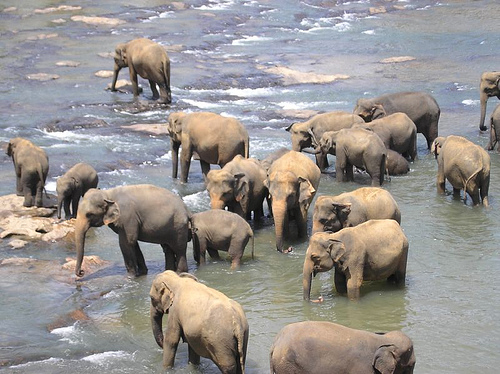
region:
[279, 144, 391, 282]
The elephants are visible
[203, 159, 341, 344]
The elephants are visible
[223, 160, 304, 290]
The elephants are visible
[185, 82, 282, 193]
The elephants are visible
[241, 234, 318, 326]
The elephants are visible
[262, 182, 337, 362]
The elephants are visible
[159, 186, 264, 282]
The elephants are visible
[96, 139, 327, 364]
The elephants are visible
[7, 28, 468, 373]
Many elephants are in the water.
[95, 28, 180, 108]
The elephant is drinking water.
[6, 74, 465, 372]
The elephants are grey.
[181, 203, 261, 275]
This is a baby elephant.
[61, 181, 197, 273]
The elephant is grey.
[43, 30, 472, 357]
The water is shallow.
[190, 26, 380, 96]
The water is moving.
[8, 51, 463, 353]
The elephants are together.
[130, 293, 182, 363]
The trunk is long.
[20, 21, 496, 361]
The sun is shining.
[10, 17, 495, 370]
herd of asian female elephants with young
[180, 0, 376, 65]
white caps on the water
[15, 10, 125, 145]
Rocks strewn across the waterway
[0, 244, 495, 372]
water does not go high up the legs of the elephants.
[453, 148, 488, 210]
a hair tipped tail on an elephant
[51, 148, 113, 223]
a very young elephant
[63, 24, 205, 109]
an elephant going off on it's own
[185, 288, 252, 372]
a large wet spot on a hind quarter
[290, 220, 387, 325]
the trunk curled up in the water.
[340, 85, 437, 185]
one elephant decides to sit down.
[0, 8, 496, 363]
A large group of elephants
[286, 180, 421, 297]
A side view of two elephants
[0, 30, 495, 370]
Elephants are in water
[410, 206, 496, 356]
The water is dirty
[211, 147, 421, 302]
Elephants have dried mud on their bodies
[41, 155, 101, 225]
A younger elephant is in the background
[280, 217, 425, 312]
Elephant is knee deep in water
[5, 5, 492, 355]
Photo was taken outdoors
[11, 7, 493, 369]
Photo was taken in the daytime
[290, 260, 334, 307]
Elephant's trunk is in the water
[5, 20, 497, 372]
Group of elephants standing in the water.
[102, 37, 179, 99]
Gray elephant drinking water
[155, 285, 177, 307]
Ear of an elephant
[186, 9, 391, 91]
Shallow water with small waves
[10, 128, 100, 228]
Two young elephants standing on a rock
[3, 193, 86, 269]
Rock standing above the waterline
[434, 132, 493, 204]
Elephant shaking it's tail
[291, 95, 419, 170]
Elephants standing together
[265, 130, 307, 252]
Elephant pulling it's trunk from the water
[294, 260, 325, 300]
Long gray trunk of an elephant